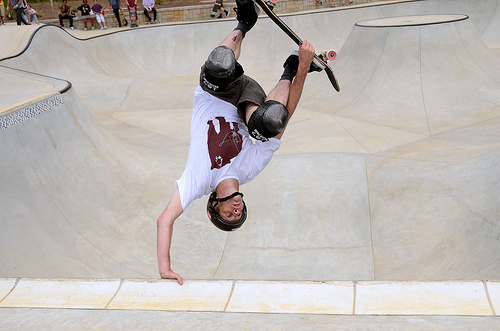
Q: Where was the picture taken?
A: It was taken at the skate park.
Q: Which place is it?
A: It is a skate park.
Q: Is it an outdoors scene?
A: Yes, it is outdoors.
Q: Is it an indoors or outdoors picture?
A: It is outdoors.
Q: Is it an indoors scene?
A: No, it is outdoors.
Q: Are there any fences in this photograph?
A: No, there are no fences.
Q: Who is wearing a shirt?
A: The boy is wearing a shirt.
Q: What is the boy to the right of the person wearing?
A: The boy is wearing a shirt.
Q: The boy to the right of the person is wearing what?
A: The boy is wearing a shirt.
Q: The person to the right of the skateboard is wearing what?
A: The boy is wearing a shirt.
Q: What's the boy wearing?
A: The boy is wearing a shirt.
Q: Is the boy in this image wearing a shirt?
A: Yes, the boy is wearing a shirt.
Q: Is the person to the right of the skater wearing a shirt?
A: Yes, the boy is wearing a shirt.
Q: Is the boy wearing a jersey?
A: No, the boy is wearing a shirt.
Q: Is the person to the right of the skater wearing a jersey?
A: No, the boy is wearing a shirt.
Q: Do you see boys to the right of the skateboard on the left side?
A: Yes, there is a boy to the right of the skateboard.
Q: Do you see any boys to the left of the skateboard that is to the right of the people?
A: No, the boy is to the right of the skateboard.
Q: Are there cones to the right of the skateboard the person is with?
A: No, there is a boy to the right of the skateboard.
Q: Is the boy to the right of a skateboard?
A: Yes, the boy is to the right of a skateboard.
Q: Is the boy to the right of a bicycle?
A: No, the boy is to the right of a skateboard.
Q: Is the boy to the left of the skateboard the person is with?
A: No, the boy is to the right of the skateboard.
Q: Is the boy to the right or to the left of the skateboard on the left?
A: The boy is to the right of the skateboard.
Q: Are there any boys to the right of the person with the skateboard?
A: Yes, there is a boy to the right of the person.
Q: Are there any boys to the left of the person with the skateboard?
A: No, the boy is to the right of the person.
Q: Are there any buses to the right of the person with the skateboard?
A: No, there is a boy to the right of the person.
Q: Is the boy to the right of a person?
A: Yes, the boy is to the right of a person.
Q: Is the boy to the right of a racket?
A: No, the boy is to the right of a person.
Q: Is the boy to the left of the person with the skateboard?
A: No, the boy is to the right of the person.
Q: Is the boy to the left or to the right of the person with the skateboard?
A: The boy is to the right of the person.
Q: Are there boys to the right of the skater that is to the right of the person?
A: Yes, there is a boy to the right of the skater.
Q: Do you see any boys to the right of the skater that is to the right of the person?
A: Yes, there is a boy to the right of the skater.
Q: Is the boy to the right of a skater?
A: Yes, the boy is to the right of a skater.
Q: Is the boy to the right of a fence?
A: No, the boy is to the right of a skater.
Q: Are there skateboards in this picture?
A: Yes, there is a skateboard.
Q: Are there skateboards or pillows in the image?
A: Yes, there is a skateboard.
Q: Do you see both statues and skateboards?
A: No, there is a skateboard but no statues.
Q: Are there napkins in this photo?
A: No, there are no napkins.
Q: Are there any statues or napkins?
A: No, there are no napkins or statues.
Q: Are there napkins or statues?
A: No, there are no napkins or statues.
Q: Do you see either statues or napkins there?
A: No, there are no napkins or statues.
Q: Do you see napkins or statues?
A: No, there are no napkins or statues.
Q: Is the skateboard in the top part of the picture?
A: Yes, the skateboard is in the top of the image.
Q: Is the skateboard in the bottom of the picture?
A: No, the skateboard is in the top of the image.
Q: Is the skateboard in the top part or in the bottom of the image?
A: The skateboard is in the top of the image.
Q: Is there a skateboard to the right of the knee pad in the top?
A: Yes, there is a skateboard to the right of the knee pad.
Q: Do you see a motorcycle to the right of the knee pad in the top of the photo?
A: No, there is a skateboard to the right of the knee pad.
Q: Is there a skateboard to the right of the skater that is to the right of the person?
A: Yes, there is a skateboard to the right of the skater.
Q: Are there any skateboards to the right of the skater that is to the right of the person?
A: Yes, there is a skateboard to the right of the skater.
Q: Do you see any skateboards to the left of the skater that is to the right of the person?
A: No, the skateboard is to the right of the skater.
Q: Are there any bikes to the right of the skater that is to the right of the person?
A: No, there is a skateboard to the right of the skater.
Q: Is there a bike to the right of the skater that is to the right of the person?
A: No, there is a skateboard to the right of the skater.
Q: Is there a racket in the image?
A: No, there are no rackets.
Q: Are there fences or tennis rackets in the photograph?
A: No, there are no tennis rackets or fences.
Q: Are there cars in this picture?
A: No, there are no cars.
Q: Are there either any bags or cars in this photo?
A: No, there are no cars or bags.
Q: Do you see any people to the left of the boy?
A: Yes, there is a person to the left of the boy.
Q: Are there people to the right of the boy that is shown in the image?
A: No, the person is to the left of the boy.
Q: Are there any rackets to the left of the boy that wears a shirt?
A: No, there is a person to the left of the boy.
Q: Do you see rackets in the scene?
A: No, there are no rackets.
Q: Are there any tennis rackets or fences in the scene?
A: No, there are no tennis rackets or fences.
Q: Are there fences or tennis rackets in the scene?
A: No, there are no tennis rackets or fences.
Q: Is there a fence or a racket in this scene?
A: No, there are no rackets or fences.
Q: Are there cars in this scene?
A: No, there are no cars.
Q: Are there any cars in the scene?
A: No, there are no cars.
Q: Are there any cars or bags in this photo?
A: No, there are no cars or bags.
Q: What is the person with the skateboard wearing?
A: The person is wearing a shirt.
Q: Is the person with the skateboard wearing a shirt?
A: Yes, the person is wearing a shirt.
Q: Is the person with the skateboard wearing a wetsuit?
A: No, the person is wearing a shirt.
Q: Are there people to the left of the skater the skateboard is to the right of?
A: Yes, there is a person to the left of the skater.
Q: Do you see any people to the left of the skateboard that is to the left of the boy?
A: Yes, there is a person to the left of the skateboard.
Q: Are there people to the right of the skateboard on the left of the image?
A: No, the person is to the left of the skateboard.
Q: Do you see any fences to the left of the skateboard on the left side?
A: No, there is a person to the left of the skateboard.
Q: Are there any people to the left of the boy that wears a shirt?
A: Yes, there is a person to the left of the boy.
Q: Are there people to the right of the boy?
A: No, the person is to the left of the boy.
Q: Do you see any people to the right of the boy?
A: No, the person is to the left of the boy.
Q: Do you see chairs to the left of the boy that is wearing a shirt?
A: No, there is a person to the left of the boy.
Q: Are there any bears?
A: Yes, there is a bear.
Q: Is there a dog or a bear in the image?
A: Yes, there is a bear.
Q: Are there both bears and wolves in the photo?
A: No, there is a bear but no wolves.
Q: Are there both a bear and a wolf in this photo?
A: No, there is a bear but no wolves.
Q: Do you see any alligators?
A: No, there are no alligators.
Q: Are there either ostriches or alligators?
A: No, there are no alligators or ostriches.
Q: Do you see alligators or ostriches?
A: No, there are no alligators or ostriches.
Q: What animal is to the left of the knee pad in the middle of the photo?
A: The animal is a bear.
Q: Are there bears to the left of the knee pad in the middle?
A: Yes, there is a bear to the left of the knee pad.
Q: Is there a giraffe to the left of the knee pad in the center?
A: No, there is a bear to the left of the knee pad.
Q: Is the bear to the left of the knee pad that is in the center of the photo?
A: Yes, the bear is to the left of the knee pad.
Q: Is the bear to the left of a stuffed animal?
A: No, the bear is to the left of the knee pad.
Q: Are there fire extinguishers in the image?
A: No, there are no fire extinguishers.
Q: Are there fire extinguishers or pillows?
A: No, there are no fire extinguishers or pillows.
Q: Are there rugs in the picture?
A: No, there are no rugs.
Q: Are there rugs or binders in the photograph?
A: No, there are no rugs or binders.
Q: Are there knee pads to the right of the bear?
A: Yes, there is a knee pad to the right of the bear.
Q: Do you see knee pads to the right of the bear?
A: Yes, there is a knee pad to the right of the bear.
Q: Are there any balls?
A: No, there are no balls.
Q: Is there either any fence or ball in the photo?
A: No, there are no balls or fences.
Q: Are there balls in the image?
A: No, there are no balls.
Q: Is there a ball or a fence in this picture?
A: No, there are no balls or fences.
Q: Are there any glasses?
A: No, there are no glasses.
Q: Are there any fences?
A: No, there are no fences.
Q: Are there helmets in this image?
A: Yes, there is a helmet.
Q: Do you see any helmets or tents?
A: Yes, there is a helmet.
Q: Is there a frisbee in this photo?
A: No, there are no frisbees.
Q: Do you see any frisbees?
A: No, there are no frisbees.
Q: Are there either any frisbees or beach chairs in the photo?
A: No, there are no frisbees or beach chairs.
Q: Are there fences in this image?
A: No, there are no fences.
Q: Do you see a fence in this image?
A: No, there are no fences.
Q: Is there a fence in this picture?
A: No, there are no fences.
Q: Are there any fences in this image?
A: No, there are no fences.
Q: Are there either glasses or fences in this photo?
A: No, there are no fences or glasses.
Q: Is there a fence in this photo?
A: No, there are no fences.